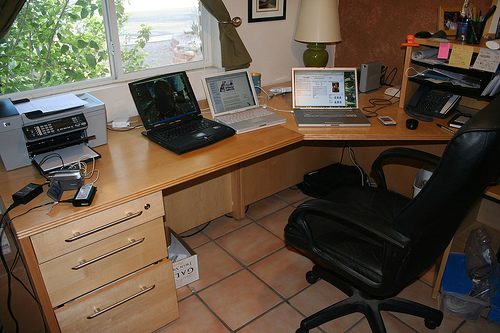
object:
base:
[294, 267, 443, 333]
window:
[1, 0, 116, 100]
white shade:
[292, 0, 341, 45]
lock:
[144, 204, 151, 211]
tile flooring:
[125, 184, 498, 330]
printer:
[1, 91, 117, 174]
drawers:
[30, 190, 181, 333]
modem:
[359, 60, 384, 93]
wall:
[346, 5, 411, 64]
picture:
[247, 0, 287, 24]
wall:
[2, 0, 339, 150]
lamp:
[293, 0, 341, 69]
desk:
[0, 79, 500, 333]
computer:
[291, 66, 373, 127]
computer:
[201, 69, 287, 134]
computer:
[128, 71, 237, 156]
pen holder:
[451, 8, 488, 43]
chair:
[283, 98, 500, 333]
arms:
[248, 184, 415, 253]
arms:
[369, 147, 442, 190]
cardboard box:
[164, 225, 200, 289]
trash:
[165, 228, 191, 264]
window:
[0, 0, 211, 96]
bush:
[13, 55, 102, 77]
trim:
[114, 73, 118, 81]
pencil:
[482, 8, 484, 25]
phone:
[404, 85, 463, 122]